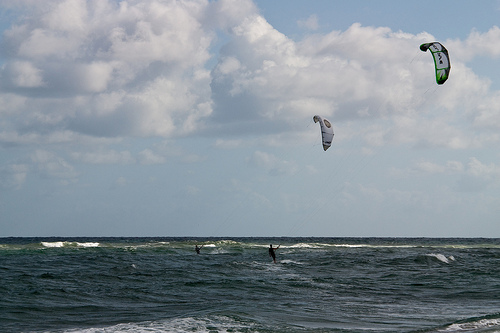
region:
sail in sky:
[405, 34, 467, 97]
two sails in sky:
[284, 23, 461, 164]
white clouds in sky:
[12, 6, 472, 131]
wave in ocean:
[6, 238, 419, 263]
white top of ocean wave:
[29, 236, 108, 252]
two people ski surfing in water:
[180, 33, 460, 280]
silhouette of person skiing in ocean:
[259, 237, 286, 262]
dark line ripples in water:
[78, 260, 168, 292]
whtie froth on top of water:
[429, 251, 462, 269]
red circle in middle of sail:
[315, 114, 335, 131]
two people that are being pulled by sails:
[167, 17, 468, 271]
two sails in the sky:
[297, 24, 457, 174]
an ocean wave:
[387, 247, 461, 276]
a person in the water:
[257, 230, 288, 265]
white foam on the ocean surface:
[84, 307, 240, 332]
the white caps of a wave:
[36, 233, 105, 255]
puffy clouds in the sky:
[13, 13, 219, 150]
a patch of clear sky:
[430, 2, 491, 32]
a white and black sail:
[310, 111, 339, 152]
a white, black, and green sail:
[419, 35, 459, 85]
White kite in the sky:
[311, 106, 336, 153]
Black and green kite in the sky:
[418, 33, 460, 90]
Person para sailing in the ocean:
[261, 236, 285, 267]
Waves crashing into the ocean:
[28, 233, 114, 254]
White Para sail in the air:
[298, 101, 355, 162]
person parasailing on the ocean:
[188, 237, 205, 259]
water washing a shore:
[381, 285, 492, 330]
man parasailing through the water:
[253, 230, 293, 265]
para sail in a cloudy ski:
[301, 100, 357, 158]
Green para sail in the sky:
[407, 25, 459, 99]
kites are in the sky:
[200, 10, 391, 137]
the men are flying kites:
[136, 186, 384, 319]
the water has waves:
[51, 216, 84, 259]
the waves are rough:
[80, 217, 167, 312]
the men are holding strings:
[237, 195, 336, 315]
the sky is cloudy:
[111, 34, 349, 226]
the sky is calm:
[74, 166, 299, 299]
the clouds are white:
[67, 32, 261, 139]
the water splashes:
[157, 286, 216, 330]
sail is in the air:
[415, 39, 450, 86]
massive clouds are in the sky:
[0, 2, 499, 186]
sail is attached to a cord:
[419, 40, 451, 86]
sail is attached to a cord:
[309, 113, 334, 150]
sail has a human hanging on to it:
[418, 40, 450, 85]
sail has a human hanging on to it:
[310, 113, 335, 152]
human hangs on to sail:
[264, 240, 279, 264]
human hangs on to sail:
[193, 243, 203, 253]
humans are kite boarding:
[192, 242, 282, 262]